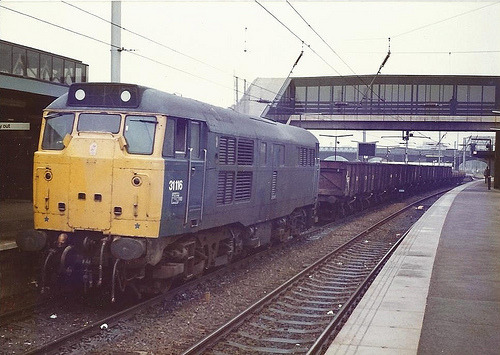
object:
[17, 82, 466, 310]
train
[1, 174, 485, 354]
tracks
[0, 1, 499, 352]
station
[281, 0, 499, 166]
cables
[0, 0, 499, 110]
sky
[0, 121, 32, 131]
sign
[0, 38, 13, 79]
windows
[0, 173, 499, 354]
gravel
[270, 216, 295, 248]
wheels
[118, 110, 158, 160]
windows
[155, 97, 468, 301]
side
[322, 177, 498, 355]
walkway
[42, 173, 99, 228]
steel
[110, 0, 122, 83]
pole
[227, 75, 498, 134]
bridge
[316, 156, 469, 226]
cars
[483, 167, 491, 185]
person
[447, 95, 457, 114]
person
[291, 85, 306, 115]
windows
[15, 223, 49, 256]
oval bumpers